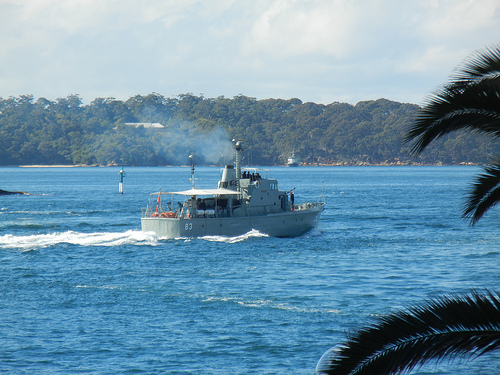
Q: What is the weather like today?
A: It is cloudy.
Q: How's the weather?
A: It is cloudy.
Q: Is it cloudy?
A: Yes, it is cloudy.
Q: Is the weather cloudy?
A: Yes, it is cloudy.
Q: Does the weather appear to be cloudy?
A: Yes, it is cloudy.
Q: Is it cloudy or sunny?
A: It is cloudy.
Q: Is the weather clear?
A: No, it is cloudy.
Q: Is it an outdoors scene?
A: Yes, it is outdoors.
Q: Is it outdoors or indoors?
A: It is outdoors.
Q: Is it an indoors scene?
A: No, it is outdoors.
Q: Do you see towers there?
A: No, there are no towers.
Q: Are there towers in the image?
A: No, there are no towers.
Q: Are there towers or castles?
A: No, there are no towers or castles.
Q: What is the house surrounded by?
A: The house is surrounded by the trees.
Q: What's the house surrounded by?
A: The house is surrounded by the trees.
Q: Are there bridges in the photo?
A: Yes, there is a bridge.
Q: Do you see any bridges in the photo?
A: Yes, there is a bridge.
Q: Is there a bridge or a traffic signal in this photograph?
A: Yes, there is a bridge.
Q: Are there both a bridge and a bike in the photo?
A: No, there is a bridge but no bikes.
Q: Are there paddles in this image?
A: No, there are no paddles.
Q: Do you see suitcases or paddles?
A: No, there are no paddles or suitcases.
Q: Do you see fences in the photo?
A: No, there are no fences.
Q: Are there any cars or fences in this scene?
A: No, there are no fences or cars.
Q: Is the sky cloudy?
A: Yes, the sky is cloudy.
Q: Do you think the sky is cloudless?
A: No, the sky is cloudy.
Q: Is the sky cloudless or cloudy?
A: The sky is cloudy.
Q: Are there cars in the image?
A: No, there are no cars.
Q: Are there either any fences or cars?
A: No, there are no cars or fences.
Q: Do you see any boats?
A: Yes, there is a boat.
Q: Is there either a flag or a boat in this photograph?
A: Yes, there is a boat.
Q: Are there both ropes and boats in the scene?
A: No, there is a boat but no ropes.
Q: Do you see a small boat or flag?
A: Yes, there is a small boat.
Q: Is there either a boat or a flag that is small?
A: Yes, the boat is small.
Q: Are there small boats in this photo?
A: Yes, there is a small boat.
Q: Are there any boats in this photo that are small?
A: Yes, there is a boat that is small.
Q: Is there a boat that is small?
A: Yes, there is a boat that is small.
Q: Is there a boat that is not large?
A: Yes, there is a small boat.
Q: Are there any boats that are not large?
A: Yes, there is a small boat.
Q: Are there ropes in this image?
A: No, there are no ropes.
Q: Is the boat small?
A: Yes, the boat is small.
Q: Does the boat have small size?
A: Yes, the boat is small.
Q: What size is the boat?
A: The boat is small.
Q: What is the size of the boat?
A: The boat is small.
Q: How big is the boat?
A: The boat is small.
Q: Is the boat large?
A: No, the boat is small.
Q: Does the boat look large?
A: No, the boat is small.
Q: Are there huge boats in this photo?
A: No, there is a boat but it is small.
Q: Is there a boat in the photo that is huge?
A: No, there is a boat but it is small.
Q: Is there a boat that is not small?
A: No, there is a boat but it is small.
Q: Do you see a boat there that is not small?
A: No, there is a boat but it is small.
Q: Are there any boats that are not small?
A: No, there is a boat but it is small.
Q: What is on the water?
A: The boat is on the water.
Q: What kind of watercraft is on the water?
A: The watercraft is a boat.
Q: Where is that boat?
A: The boat is on the water.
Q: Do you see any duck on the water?
A: No, there is a boat on the water.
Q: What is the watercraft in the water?
A: The watercraft is a boat.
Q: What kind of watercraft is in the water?
A: The watercraft is a boat.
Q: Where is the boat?
A: The boat is in the water.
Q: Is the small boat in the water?
A: Yes, the boat is in the water.